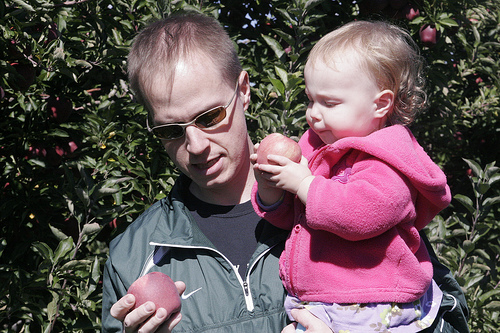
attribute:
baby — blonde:
[250, 15, 457, 329]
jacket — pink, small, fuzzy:
[241, 123, 454, 305]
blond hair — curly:
[301, 16, 431, 151]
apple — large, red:
[120, 267, 183, 331]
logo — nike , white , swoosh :
[181, 285, 204, 301]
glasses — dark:
[140, 100, 240, 144]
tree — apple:
[3, 4, 97, 325]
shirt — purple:
[280, 304, 444, 329]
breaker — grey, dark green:
[96, 177, 302, 332]